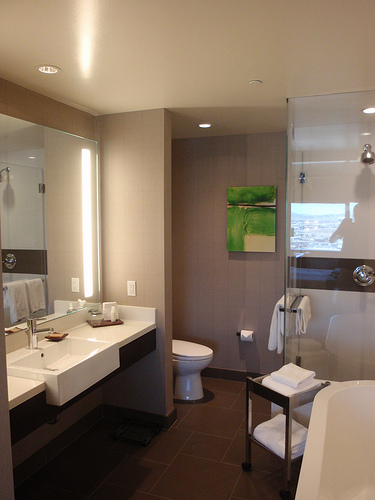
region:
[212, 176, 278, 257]
the picture is on the wall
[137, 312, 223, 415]
the toilet seat is down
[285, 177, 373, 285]
a man reflected in the glass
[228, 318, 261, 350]
a roll of toilet paper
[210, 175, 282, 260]
the picture is mainly green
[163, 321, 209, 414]
the toilet is white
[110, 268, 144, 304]
a white outlet on the wall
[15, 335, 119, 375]
a square sink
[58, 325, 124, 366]
light reflecting on the sink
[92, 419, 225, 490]
the floor is brown tiles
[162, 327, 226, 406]
white toilet in bathroom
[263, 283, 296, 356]
towels hanging on rack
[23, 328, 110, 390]
square sink in vanity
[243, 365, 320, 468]
cart with folded towels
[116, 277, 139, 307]
electrical outlet on wall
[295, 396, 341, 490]
edge of white bathtub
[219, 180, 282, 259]
modern painting on wall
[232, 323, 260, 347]
toilet paper on rack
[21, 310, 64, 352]
metal faucet over sink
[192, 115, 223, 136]
recessed light in ceiling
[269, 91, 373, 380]
the shower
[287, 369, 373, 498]
the tub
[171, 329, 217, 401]
the toilet seat is down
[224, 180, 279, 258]
the picture on the wall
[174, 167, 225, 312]
the wall is tiled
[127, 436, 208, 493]
the floor has large tiles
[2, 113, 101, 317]
the mirror on the wall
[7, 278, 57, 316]
the white towels hanging on the towel rod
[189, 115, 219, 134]
the light on the ceiling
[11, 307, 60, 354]
Metal water fixture atop a sink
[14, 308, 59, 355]
Silver water faucet atop a sink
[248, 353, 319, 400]
folded white cotton towels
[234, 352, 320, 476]
folded towels on a wooden rack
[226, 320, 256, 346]
toilet paper on a roll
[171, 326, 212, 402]
toilet in an alcove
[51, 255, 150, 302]
electrical outlet reflected in mirror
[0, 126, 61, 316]
shower reflected in bathroom mirror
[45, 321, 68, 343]
soap dish on top of a sink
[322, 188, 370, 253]
reflection of photographer in glass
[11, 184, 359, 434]
a picture of a bathroom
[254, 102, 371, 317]
a view of water outside a window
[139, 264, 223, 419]
a toilet seat in the corner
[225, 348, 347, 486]
a towel stand by the tub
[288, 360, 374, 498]
a white bathtub in the restroom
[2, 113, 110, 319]
mirror on the wall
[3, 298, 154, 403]
a bathroom sink and counter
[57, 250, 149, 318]
an electric outlet on the wall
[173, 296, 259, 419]
a toilet paper roll near the toilet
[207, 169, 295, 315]
a picture in the bathroom